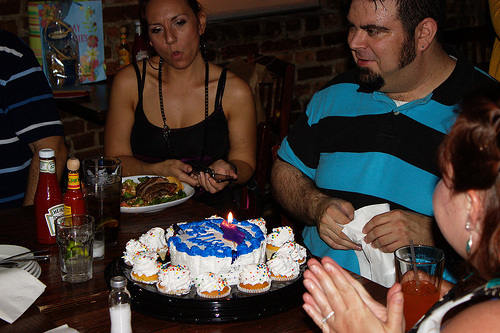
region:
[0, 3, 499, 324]
large group gathered for birthday celebration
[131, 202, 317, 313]
blue icing on top of birthday cake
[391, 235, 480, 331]
half full glass of orange soda or juice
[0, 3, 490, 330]
family singing happy birthday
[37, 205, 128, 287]
small glass of water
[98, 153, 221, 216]
plate with steak salad on it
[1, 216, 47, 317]
stack of clean plates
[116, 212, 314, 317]
candle lit on top of birthday cake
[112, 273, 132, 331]
salt shaker on table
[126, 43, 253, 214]
black necklace around woman's neck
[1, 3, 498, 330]
group gathered for a birthday celebration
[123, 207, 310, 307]
small birthday cake with cupcakes around it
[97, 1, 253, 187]
woman wearing black tank top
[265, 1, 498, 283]
man wearing black and blue striped shirt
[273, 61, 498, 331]
woman with engagement ring on left ring finger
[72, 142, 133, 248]
glass of cola sitting on wood table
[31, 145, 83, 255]
ketchup and hot sauce on table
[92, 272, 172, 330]
salt shaker on table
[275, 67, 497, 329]
woman wearing silver earrings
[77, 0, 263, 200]
woman with cellphone in her left hand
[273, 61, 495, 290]
black and blue striped shirt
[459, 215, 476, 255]
silver earring in the woman's ear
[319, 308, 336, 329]
silver ring on the woman's finger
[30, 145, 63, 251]
red and white ketchup bottle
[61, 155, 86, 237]
red and yellow hot sauce bottle with wood cap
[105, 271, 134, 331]
clear, gray and white salt shaker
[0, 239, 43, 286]
stack of white plates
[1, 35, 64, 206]
black shirt with blue and white stripes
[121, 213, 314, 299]
cupcakes with white frosting and sprinkles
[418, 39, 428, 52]
small earring in the man's ear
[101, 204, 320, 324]
A tray of cupcakes and a cake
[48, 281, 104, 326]
The table is made of wood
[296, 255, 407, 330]
The hands of the woman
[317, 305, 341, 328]
The woman has on a ring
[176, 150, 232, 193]
The woman is holding a phone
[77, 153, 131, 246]
A glass with a drink in it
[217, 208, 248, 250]
The candle is lit on the cake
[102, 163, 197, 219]
A plate of food on the table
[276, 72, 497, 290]
The man has on a black and blue striped shirt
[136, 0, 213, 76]
The head of the man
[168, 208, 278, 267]
Birthday cake with a single candle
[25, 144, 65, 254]
Bottle of heinz ketchup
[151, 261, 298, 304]
Cupcakes with multi colored sprinkles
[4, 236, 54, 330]
Stack of plates covered with a napkin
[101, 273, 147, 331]
Half full salt shaker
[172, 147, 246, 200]
Hands grasping a cell phone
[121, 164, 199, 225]
An Untouched plate of Food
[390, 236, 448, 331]
Half Full Drink Glass with a Straw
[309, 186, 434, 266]
Mans hands holding a napkin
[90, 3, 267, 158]
Woman with her mouth slightly opened